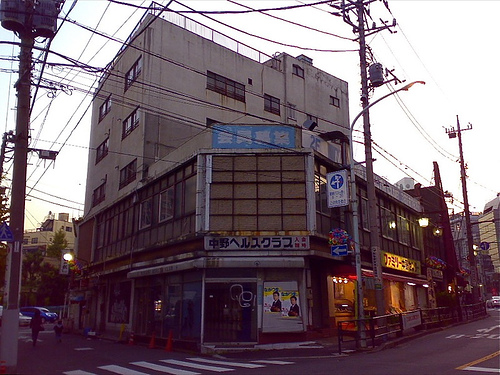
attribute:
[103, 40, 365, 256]
building — brown, old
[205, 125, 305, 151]
sign — blue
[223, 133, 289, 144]
writing — chinese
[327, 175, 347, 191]
circle — blue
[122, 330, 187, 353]
cones — three, orange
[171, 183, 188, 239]
window — long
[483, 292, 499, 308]
car — silver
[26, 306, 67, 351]
people — walking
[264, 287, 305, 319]
poster — yellow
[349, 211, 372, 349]
pole — grey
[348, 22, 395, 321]
pole — electrical, high, wooden, brown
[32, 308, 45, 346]
person — walking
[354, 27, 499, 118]
sky — cloudy, white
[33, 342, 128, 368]
road — grey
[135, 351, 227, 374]
lines — white, crossing, painted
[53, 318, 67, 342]
child — walking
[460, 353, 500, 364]
line — yellow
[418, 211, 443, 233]
lights — on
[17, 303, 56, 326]
cars — parked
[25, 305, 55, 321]
car — blue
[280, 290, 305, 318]
sign — black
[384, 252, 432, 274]
sign — yellow